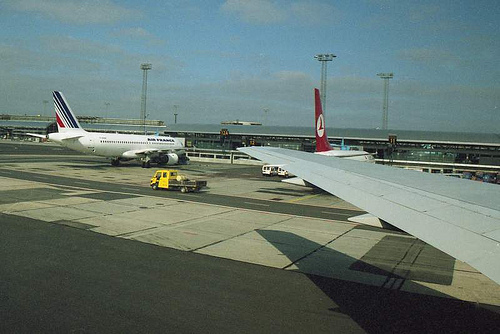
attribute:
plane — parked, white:
[25, 79, 205, 180]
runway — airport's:
[3, 166, 498, 307]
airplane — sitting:
[311, 87, 376, 163]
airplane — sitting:
[26, 90, 191, 169]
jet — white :
[26, 84, 191, 164]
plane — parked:
[21, 78, 220, 165]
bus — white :
[259, 164, 279, 176]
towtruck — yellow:
[145, 169, 207, 196]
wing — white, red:
[309, 87, 334, 150]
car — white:
[259, 163, 272, 179]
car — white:
[273, 163, 290, 176]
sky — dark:
[0, 6, 499, 131]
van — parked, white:
[258, 161, 275, 177]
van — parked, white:
[275, 163, 288, 176]